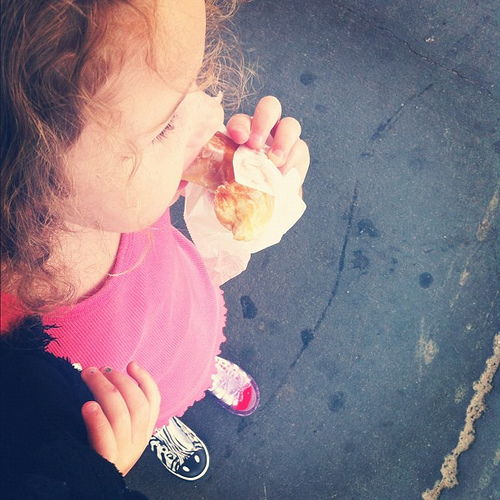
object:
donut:
[181, 131, 274, 241]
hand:
[226, 95, 311, 200]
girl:
[1, 0, 311, 482]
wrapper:
[183, 139, 307, 287]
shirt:
[2, 207, 229, 430]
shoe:
[210, 353, 261, 417]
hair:
[1, 0, 266, 316]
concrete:
[123, 1, 499, 499]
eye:
[149, 112, 175, 146]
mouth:
[175, 144, 207, 192]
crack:
[332, 0, 499, 104]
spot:
[299, 66, 317, 87]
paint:
[105, 367, 112, 373]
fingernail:
[99, 365, 114, 376]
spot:
[314, 101, 328, 114]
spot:
[238, 293, 259, 321]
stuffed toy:
[0, 312, 151, 500]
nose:
[189, 88, 226, 150]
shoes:
[148, 412, 210, 480]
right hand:
[80, 360, 163, 478]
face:
[63, 0, 226, 234]